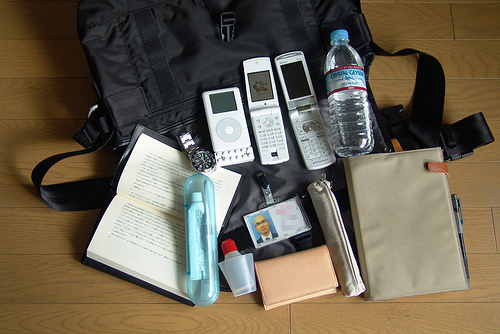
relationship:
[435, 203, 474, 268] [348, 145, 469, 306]
pen clasped onto diary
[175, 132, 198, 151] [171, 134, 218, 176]
strap connected to watch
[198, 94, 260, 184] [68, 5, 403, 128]
ipod laying on bag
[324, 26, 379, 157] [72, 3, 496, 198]
bottle laying on bag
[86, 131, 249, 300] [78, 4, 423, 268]
book laying on bag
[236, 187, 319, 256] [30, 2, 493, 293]
id laying on bag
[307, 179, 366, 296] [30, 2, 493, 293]
pouch on top of bag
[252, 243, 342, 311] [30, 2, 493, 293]
wallet on top of bag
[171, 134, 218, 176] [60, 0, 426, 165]
watch on top of bag